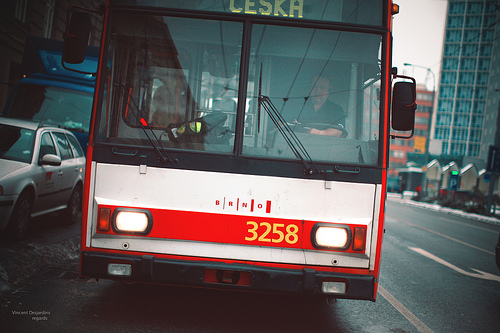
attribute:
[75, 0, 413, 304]
bus — red, white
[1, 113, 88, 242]
car — gray, blue, parked, white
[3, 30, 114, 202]
truck — blue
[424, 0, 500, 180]
buildings — tall, large, glass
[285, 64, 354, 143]
man — driving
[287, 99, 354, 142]
shirt — black, dark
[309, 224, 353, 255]
headlights — on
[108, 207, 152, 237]
headlights — on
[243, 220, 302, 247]
numbers — yellow, identification, 3258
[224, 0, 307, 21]
sign — destination, electronic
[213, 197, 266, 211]
letters — small, red, yellow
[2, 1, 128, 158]
building — red, orange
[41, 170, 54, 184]
decal — red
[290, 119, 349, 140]
wheel — black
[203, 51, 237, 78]
mirror — rearview, black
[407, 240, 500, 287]
marking — white